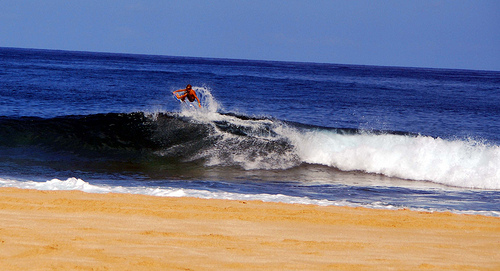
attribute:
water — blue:
[0, 47, 497, 209]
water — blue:
[69, 56, 473, 168]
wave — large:
[0, 82, 500, 194]